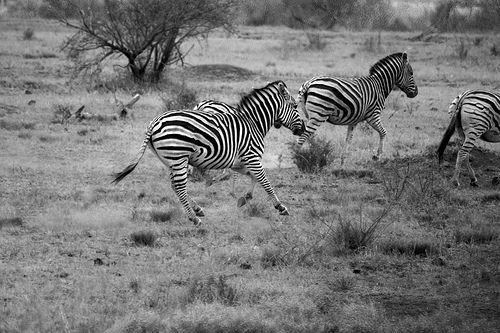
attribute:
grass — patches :
[2, 18, 499, 330]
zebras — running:
[114, 48, 495, 205]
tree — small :
[112, 14, 233, 86]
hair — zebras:
[238, 76, 277, 109]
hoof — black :
[279, 207, 289, 216]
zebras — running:
[151, 69, 368, 200]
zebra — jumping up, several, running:
[111, 76, 309, 229]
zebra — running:
[298, 49, 420, 163]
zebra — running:
[436, 87, 498, 187]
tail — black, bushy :
[110, 130, 160, 187]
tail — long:
[104, 131, 160, 186]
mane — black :
[233, 76, 281, 112]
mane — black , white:
[366, 50, 408, 72]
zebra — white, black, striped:
[100, 75, 315, 242]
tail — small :
[103, 114, 179, 216]